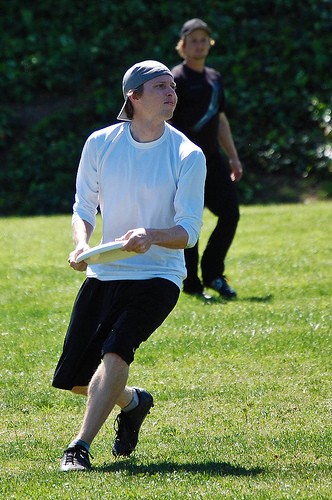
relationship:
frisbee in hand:
[77, 236, 138, 268] [114, 228, 151, 256]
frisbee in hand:
[77, 236, 138, 268] [69, 241, 87, 272]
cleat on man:
[112, 389, 154, 456] [52, 59, 207, 476]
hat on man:
[183, 17, 212, 34] [179, 16, 244, 299]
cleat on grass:
[63, 446, 91, 475] [2, 202, 331, 500]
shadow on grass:
[91, 458, 263, 477] [2, 202, 331, 500]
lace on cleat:
[87, 450, 96, 459] [63, 446, 91, 475]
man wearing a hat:
[52, 59, 207, 476] [113, 55, 173, 122]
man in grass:
[179, 16, 244, 299] [2, 202, 331, 500]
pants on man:
[198, 157, 241, 284] [179, 16, 244, 299]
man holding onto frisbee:
[52, 59, 207, 476] [77, 236, 138, 268]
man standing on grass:
[52, 59, 207, 476] [2, 202, 331, 500]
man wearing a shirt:
[179, 16, 244, 299] [172, 62, 226, 152]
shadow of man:
[207, 295, 269, 305] [179, 16, 244, 299]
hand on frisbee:
[114, 228, 151, 256] [77, 236, 138, 268]